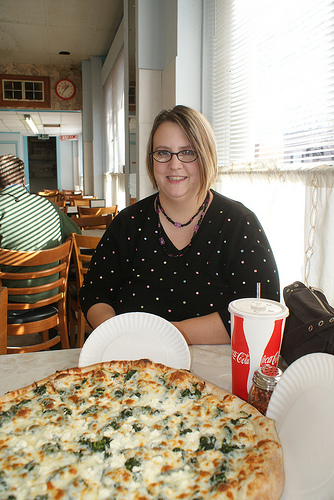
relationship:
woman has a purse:
[76, 105, 284, 344] [275, 277, 333, 369]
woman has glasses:
[76, 105, 284, 344] [149, 146, 201, 164]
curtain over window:
[208, 166, 333, 301] [201, 1, 334, 314]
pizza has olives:
[0, 356, 286, 498] [197, 432, 211, 450]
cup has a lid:
[228, 298, 290, 402] [225, 295, 291, 323]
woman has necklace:
[76, 105, 284, 344] [156, 188, 213, 230]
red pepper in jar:
[249, 387, 275, 414] [246, 365, 282, 417]